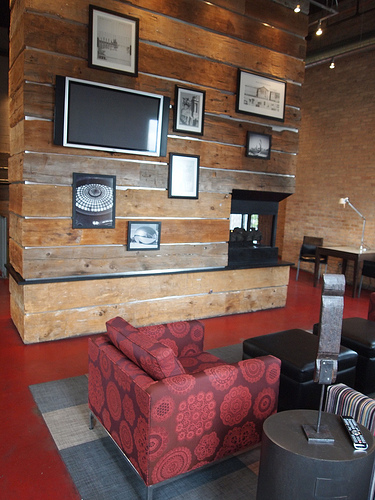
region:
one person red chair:
[86, 315, 260, 498]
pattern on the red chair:
[156, 393, 251, 449]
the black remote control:
[343, 413, 367, 451]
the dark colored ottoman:
[244, 323, 359, 421]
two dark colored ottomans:
[242, 311, 373, 408]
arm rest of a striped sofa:
[325, 380, 373, 430]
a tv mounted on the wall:
[49, 71, 169, 163]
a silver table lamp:
[338, 197, 369, 252]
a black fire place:
[228, 185, 279, 260]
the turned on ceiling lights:
[285, 1, 341, 70]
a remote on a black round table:
[269, 403, 373, 466]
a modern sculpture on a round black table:
[266, 270, 346, 453]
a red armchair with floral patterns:
[85, 314, 272, 447]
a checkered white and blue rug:
[24, 358, 92, 483]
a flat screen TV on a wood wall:
[49, 67, 172, 160]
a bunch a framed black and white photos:
[170, 12, 309, 200]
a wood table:
[316, 235, 374, 299]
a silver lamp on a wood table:
[335, 188, 374, 266]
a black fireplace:
[221, 195, 286, 272]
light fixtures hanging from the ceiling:
[259, 0, 361, 72]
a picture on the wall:
[177, 81, 206, 143]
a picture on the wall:
[126, 220, 163, 251]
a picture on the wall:
[71, 168, 122, 238]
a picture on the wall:
[168, 147, 198, 204]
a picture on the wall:
[246, 128, 270, 164]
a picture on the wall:
[235, 61, 291, 124]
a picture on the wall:
[87, 2, 142, 74]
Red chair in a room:
[76, 316, 302, 482]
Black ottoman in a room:
[229, 308, 350, 415]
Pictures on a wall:
[50, 170, 190, 285]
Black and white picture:
[72, 166, 124, 257]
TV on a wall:
[46, 60, 180, 147]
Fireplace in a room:
[224, 180, 292, 274]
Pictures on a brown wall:
[68, 13, 290, 181]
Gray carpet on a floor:
[26, 370, 177, 495]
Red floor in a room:
[10, 342, 52, 470]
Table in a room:
[292, 218, 372, 283]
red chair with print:
[79, 320, 278, 494]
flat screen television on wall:
[46, 66, 178, 164]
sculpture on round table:
[293, 267, 356, 450]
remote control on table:
[333, 410, 368, 457]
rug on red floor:
[20, 365, 84, 410]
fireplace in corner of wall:
[208, 183, 298, 282]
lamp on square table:
[319, 192, 369, 261]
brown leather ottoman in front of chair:
[238, 316, 357, 399]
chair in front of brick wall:
[291, 230, 331, 282]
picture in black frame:
[66, 167, 131, 233]